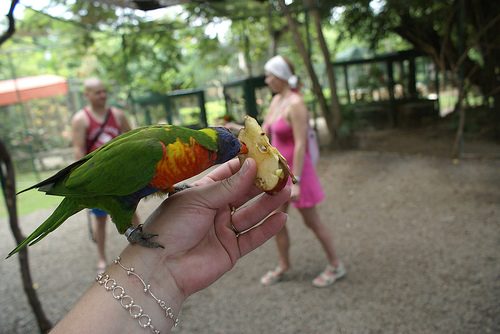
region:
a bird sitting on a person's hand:
[8, 102, 250, 324]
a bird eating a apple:
[208, 102, 296, 192]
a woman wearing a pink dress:
[263, 85, 318, 226]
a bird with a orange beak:
[211, 124, 252, 159]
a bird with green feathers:
[60, 129, 160, 210]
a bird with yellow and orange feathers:
[146, 129, 228, 188]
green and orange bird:
[110, 123, 226, 203]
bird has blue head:
[213, 118, 233, 166]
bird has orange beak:
[208, 126, 253, 166]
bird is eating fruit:
[240, 107, 303, 219]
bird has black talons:
[130, 213, 165, 258]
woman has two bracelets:
[90, 256, 132, 325]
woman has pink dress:
[247, 91, 311, 201]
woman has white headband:
[240, 50, 304, 90]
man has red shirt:
[77, 63, 143, 165]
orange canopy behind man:
[0, 66, 54, 121]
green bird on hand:
[40, 118, 222, 219]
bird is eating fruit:
[230, 84, 326, 236]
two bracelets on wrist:
[107, 244, 171, 328]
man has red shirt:
[43, 77, 143, 190]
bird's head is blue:
[213, 125, 240, 159]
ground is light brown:
[372, 174, 443, 269]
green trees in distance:
[224, 0, 461, 82]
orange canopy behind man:
[5, 73, 102, 120]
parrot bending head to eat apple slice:
[3, 113, 299, 260]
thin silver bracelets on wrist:
[90, 246, 190, 328]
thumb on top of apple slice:
[209, 120, 290, 214]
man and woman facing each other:
[67, 50, 344, 295]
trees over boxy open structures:
[120, 3, 487, 143]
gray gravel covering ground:
[6, 152, 491, 331]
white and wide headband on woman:
[257, 51, 301, 95]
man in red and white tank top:
[72, 70, 132, 152]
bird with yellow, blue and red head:
[200, 122, 247, 167]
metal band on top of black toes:
[117, 217, 168, 250]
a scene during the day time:
[5, 3, 494, 305]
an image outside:
[2, 8, 491, 327]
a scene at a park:
[3, 8, 492, 318]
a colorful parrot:
[8, 112, 263, 280]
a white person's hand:
[27, 153, 329, 330]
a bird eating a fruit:
[6, 90, 308, 291]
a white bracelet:
[77, 240, 200, 331]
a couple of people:
[58, 46, 371, 296]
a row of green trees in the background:
[11, 0, 491, 154]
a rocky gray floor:
[3, 148, 495, 332]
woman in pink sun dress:
[254, 53, 347, 287]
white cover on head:
[263, 53, 300, 95]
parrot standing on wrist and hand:
[10, 116, 293, 332]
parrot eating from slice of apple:
[5, 114, 288, 257]